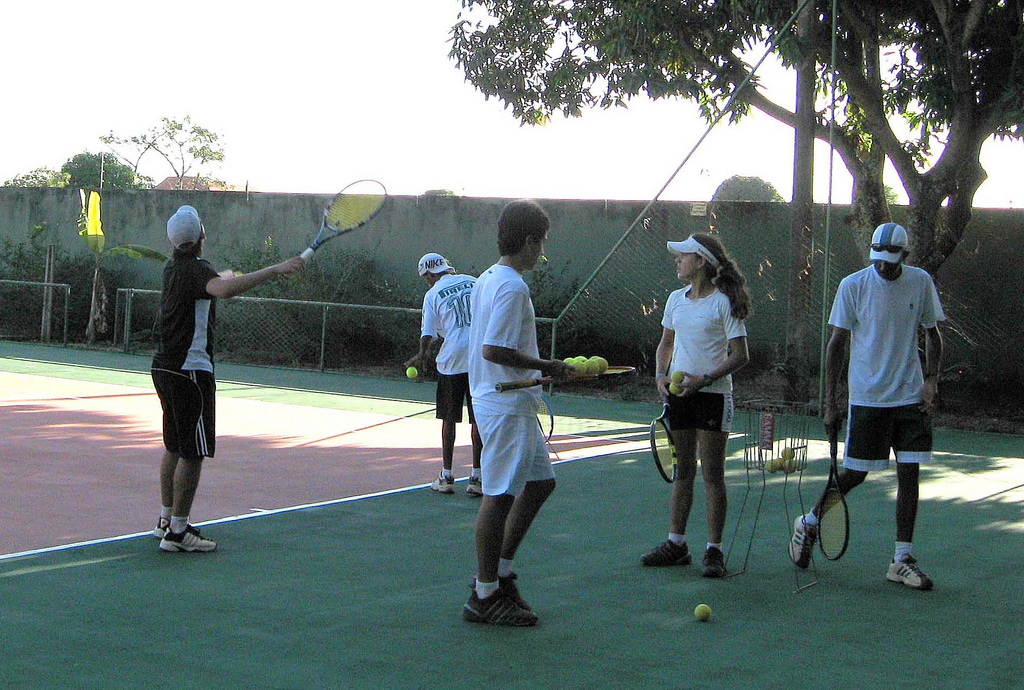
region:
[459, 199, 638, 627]
a male tennis player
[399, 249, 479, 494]
a male tennis player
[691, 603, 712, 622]
a yellow tennis ball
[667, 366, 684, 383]
a yellow tennis ball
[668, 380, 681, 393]
a yellow tennis ball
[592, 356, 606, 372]
a yellow tennis ball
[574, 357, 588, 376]
a yellow tennis ball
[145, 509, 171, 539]
shoe on persons foot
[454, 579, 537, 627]
shoe on persons foot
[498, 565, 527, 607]
shoe on persons foot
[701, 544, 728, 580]
shoe on persons foot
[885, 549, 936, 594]
shoe on persons foot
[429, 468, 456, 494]
shoe on persons foot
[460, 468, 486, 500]
shoe on persons foot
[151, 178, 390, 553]
boy holding a tennis racket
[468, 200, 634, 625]
boy holding a tennis racket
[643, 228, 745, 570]
girl holding a tennis racket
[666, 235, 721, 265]
sun visor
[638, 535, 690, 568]
right tennis shoe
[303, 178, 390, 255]
grey tennis racket with white handle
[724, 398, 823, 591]
wire bin filled with tennis balls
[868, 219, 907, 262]
blue and white ball cap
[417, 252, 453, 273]
black and white ball cap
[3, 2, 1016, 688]
several people standing near an outdoor tennis court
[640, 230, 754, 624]
tennis ball sitting in front of a woman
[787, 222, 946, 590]
man's sunglasses are resting on the brim of his hat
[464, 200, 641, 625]
man holding several tennis balls on a racket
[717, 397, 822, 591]
tennis balls sitting in a basket with long metal legs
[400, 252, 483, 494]
tennis ball beneath man's hand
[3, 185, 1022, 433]
greenery between cement wall and chain link fence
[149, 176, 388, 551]
man holding tennis racket away from his body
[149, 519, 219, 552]
shoe on persons foot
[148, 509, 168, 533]
shoe on persons foot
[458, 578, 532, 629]
shoe on persons foot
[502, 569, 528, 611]
shoe on persons foot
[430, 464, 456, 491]
shoe on persons foot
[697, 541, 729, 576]
shoe on persons foot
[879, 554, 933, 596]
shoe on persons foot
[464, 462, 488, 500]
shoe on persons foot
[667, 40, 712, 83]
green leaves on the tree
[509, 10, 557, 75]
green leaves on the tree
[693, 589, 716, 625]
tennis ball on greentop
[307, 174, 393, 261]
racket getting ready to hit ball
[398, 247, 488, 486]
boy practicing his serve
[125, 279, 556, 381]
low chain link fence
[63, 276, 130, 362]
small opening in fence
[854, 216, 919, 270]
white cap with sunglasses balanced on brim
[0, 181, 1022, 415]
cement block wall around court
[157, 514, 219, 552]
foot on the tennis player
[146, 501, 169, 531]
foot on the tennis player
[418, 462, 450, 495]
foot on the tennis player